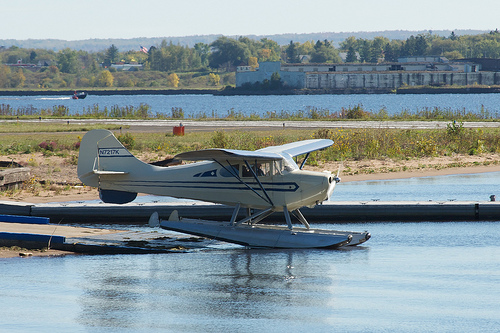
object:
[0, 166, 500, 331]
water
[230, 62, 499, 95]
house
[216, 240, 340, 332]
shade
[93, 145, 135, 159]
words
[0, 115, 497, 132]
path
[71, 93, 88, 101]
boat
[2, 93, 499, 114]
water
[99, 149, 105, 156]
black lettering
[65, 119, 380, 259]
air plane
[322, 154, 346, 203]
propellor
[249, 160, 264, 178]
man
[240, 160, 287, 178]
cockpit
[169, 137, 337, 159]
wings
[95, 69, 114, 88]
trees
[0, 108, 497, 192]
grass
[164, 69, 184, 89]
tree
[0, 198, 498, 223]
bridge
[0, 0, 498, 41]
sky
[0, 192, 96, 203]
dirt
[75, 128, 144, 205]
tail